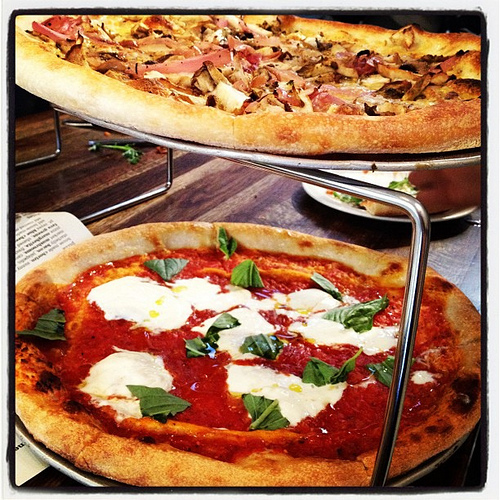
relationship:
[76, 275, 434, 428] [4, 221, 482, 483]
mozzarella on pizza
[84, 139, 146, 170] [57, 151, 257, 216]
food bits on wooden table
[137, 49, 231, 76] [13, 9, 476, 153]
ham on pizza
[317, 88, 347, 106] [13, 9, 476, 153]
red onion on pizza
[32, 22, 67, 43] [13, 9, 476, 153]
red onion on pizza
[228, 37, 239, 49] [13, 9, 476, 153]
red onion on pizza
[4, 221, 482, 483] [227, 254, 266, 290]
pizza with basil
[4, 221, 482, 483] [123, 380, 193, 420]
pizza with basil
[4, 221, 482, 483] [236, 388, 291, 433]
pizza with basil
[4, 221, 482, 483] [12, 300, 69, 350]
pizza with basil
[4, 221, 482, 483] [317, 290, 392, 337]
pizza with basil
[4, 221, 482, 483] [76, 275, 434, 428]
pizza with mozzarella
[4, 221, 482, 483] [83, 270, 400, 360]
pizza with mozzarella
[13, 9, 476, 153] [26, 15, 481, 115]
pizza with mushrooms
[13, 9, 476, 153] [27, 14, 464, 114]
pizza with ham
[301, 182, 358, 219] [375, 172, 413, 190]
plate with salad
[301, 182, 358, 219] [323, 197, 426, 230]
plate with crust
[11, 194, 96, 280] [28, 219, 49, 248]
paper with words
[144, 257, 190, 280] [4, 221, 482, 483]
basil on top pizza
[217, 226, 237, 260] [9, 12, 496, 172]
basil leaf on top pizza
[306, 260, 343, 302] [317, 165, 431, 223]
green leaf on top pizza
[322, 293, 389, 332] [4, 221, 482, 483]
basil on top of pizza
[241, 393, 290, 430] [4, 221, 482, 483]
basil on top of pizza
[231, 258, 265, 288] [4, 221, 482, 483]
basil on top of pizza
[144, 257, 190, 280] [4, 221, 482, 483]
basil on top of pizza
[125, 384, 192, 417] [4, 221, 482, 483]
basil on top of pizza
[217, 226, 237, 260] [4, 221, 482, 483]
basil leaf on top of pizza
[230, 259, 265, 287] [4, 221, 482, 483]
basil leaf on top of pizza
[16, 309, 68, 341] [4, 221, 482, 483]
basil on top of pizza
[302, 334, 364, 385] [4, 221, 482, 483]
leaves on top of pizza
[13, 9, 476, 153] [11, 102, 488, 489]
pizza on rack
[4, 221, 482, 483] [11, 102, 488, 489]
pizza on rack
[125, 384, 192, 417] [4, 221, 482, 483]
basil on pizza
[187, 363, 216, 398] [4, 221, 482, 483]
sauce on pizza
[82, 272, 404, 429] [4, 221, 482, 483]
mozzarella on pizza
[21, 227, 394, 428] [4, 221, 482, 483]
basil on pizza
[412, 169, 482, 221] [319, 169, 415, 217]
person taking slice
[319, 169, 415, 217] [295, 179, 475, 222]
slice on plate